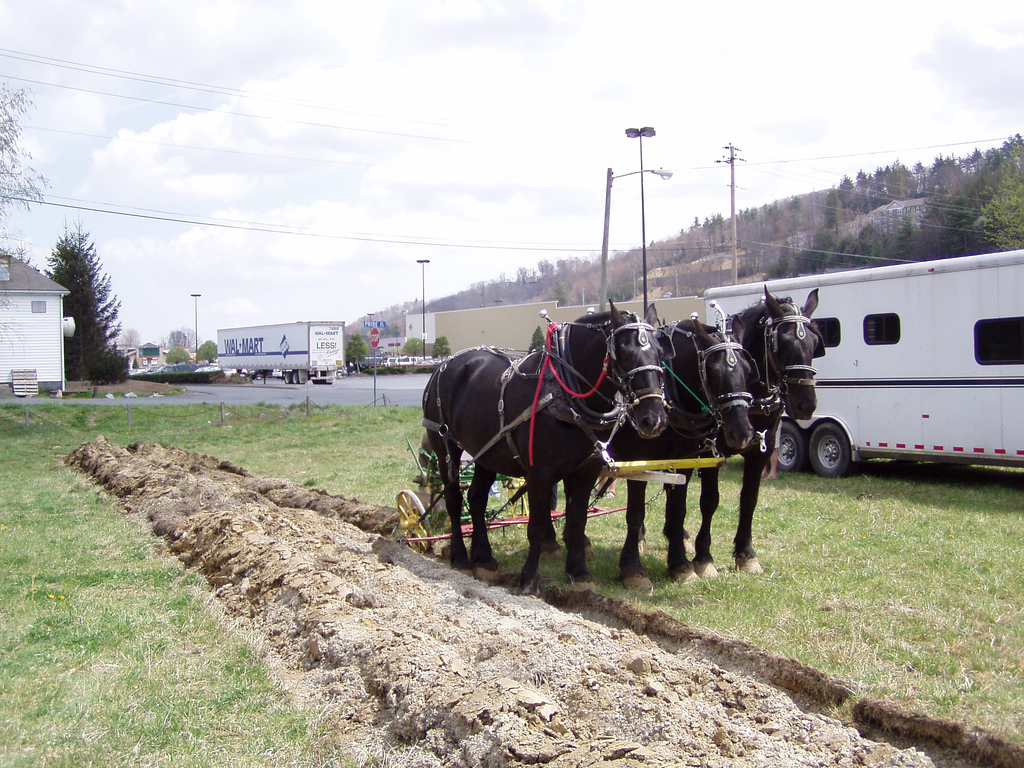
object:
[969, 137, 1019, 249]
leaves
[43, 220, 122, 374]
leaves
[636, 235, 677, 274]
leaves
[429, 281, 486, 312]
leaves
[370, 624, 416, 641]
scene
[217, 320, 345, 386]
truck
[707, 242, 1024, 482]
trailer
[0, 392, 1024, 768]
field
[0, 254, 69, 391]
house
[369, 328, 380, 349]
sign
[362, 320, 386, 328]
sign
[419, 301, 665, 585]
horse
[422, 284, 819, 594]
horse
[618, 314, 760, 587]
horse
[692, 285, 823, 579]
horse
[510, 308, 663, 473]
bridle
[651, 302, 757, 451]
bridle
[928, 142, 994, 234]
tree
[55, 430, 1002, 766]
plowed